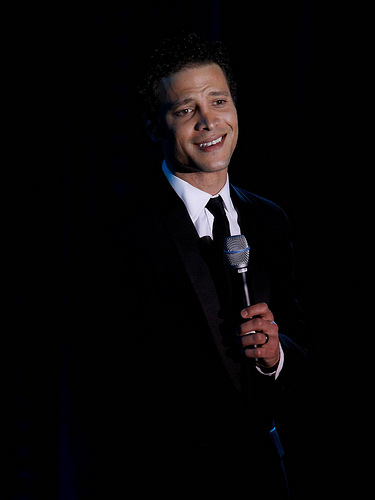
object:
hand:
[238, 302, 281, 369]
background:
[0, 1, 373, 498]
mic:
[224, 233, 264, 360]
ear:
[147, 110, 165, 139]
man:
[111, 43, 302, 500]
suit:
[104, 160, 292, 500]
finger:
[241, 301, 271, 321]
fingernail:
[239, 306, 249, 318]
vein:
[162, 76, 180, 97]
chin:
[201, 159, 230, 172]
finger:
[239, 332, 271, 348]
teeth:
[194, 134, 226, 147]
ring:
[260, 329, 270, 347]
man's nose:
[194, 100, 218, 136]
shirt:
[159, 159, 241, 241]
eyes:
[211, 96, 232, 108]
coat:
[91, 163, 341, 500]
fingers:
[244, 348, 265, 358]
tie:
[204, 197, 230, 256]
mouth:
[190, 135, 230, 147]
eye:
[171, 105, 192, 121]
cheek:
[178, 123, 193, 146]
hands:
[236, 299, 279, 359]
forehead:
[182, 70, 218, 88]